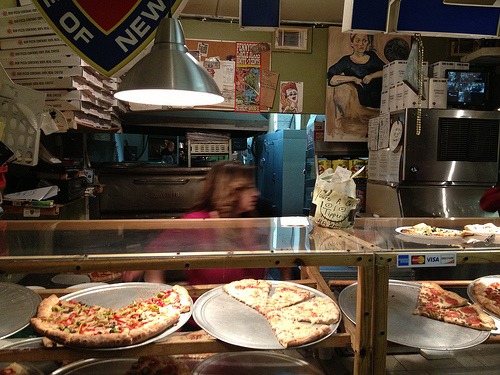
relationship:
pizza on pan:
[100, 301, 157, 328] [218, 307, 245, 318]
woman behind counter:
[215, 185, 257, 275] [357, 219, 404, 350]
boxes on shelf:
[42, 66, 84, 96] [73, 131, 117, 141]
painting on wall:
[269, 78, 299, 112] [307, 60, 320, 66]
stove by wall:
[438, 134, 493, 176] [307, 60, 320, 66]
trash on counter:
[307, 160, 357, 190] [357, 219, 404, 350]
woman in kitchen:
[215, 185, 257, 275] [253, 65, 389, 210]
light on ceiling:
[128, 21, 228, 105] [317, 4, 333, 12]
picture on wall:
[313, 38, 351, 69] [307, 60, 320, 66]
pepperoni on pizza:
[445, 298, 458, 305] [100, 301, 157, 328]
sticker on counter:
[404, 249, 432, 267] [357, 219, 404, 350]